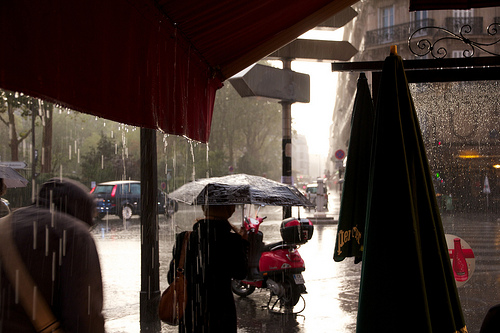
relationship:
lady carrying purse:
[165, 186, 265, 333] [159, 233, 195, 328]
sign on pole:
[263, 35, 358, 65] [278, 102, 294, 287]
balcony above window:
[353, 19, 498, 93] [404, 16, 496, 66]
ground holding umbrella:
[406, 113, 446, 158] [151, 133, 344, 239]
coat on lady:
[164, 218, 265, 332] [165, 186, 265, 333]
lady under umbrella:
[165, 186, 265, 333] [167, 171, 310, 209]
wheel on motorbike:
[230, 270, 256, 295] [240, 205, 314, 315]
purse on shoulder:
[157, 221, 200, 329] [173, 222, 195, 249]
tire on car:
[121, 206, 134, 221] [85, 170, 177, 220]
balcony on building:
[353, 19, 498, 93] [347, 29, 477, 144]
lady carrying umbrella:
[165, 186, 265, 333] [168, 164, 319, 219]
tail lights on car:
[86, 176, 118, 206] [93, 179, 175, 219]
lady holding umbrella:
[165, 186, 265, 333] [162, 162, 333, 218]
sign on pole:
[232, 64, 312, 105] [265, 104, 307, 287]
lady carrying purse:
[165, 186, 265, 333] [152, 230, 195, 328]